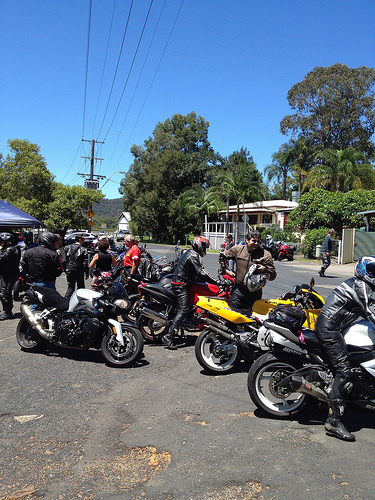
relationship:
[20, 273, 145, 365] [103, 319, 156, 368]
motorcycle has wheel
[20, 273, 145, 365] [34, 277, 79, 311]
motorcycle has seat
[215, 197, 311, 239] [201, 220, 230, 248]
house has deck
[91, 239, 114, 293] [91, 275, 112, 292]
woman in skirt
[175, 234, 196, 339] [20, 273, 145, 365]
rider on motorcycle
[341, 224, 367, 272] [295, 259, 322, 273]
fencing along sidewalk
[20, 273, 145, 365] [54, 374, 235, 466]
motorcycle on street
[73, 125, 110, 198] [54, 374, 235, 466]
pole in street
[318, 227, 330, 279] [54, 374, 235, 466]
man crossing street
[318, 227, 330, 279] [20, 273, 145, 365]
man by motorcycle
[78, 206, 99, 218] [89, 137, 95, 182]
sign on pole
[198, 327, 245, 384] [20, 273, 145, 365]
tire on motorcycle